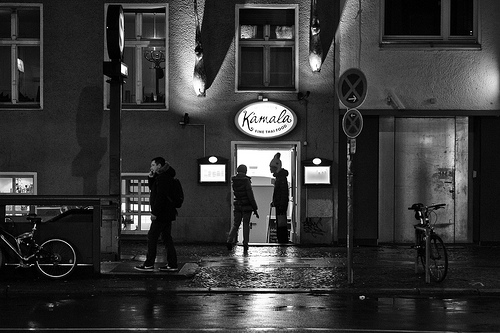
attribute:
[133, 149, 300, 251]
people — standing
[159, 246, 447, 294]
sidewalk — wet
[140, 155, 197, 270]
man — talking, walking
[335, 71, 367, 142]
signs — circular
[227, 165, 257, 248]
women — standing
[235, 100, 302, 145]
sign — oval, lit, white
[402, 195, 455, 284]
bike — parked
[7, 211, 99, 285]
bicycle — parked, leaning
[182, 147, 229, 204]
panels — lit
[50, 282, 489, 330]
street — wet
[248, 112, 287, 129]
letters — black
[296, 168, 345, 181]
screen — lit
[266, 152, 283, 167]
hat — knit